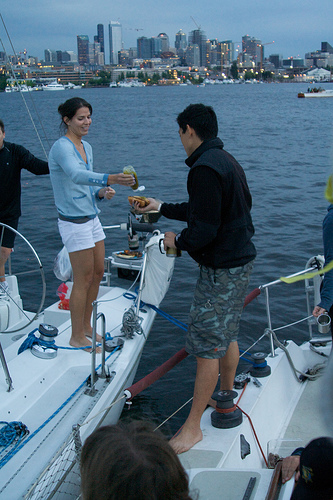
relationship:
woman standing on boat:
[41, 101, 135, 348] [9, 216, 204, 421]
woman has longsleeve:
[41, 101, 135, 348] [56, 149, 114, 187]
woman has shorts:
[41, 101, 135, 348] [46, 217, 119, 251]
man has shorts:
[141, 101, 273, 450] [46, 217, 119, 251]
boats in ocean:
[12, 229, 330, 495] [105, 88, 326, 161]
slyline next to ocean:
[12, 55, 326, 99] [105, 88, 326, 161]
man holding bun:
[141, 101, 273, 450] [125, 192, 157, 209]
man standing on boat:
[141, 101, 273, 450] [9, 216, 204, 421]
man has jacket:
[141, 101, 273, 450] [159, 152, 277, 269]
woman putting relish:
[41, 101, 135, 348] [120, 168, 149, 193]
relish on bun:
[120, 168, 149, 193] [125, 192, 157, 209]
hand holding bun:
[132, 195, 200, 217] [125, 192, 157, 209]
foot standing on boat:
[165, 420, 207, 450] [9, 216, 204, 421]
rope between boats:
[144, 307, 184, 332] [12, 229, 330, 495]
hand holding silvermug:
[157, 183, 244, 247] [154, 233, 190, 267]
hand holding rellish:
[132, 195, 200, 217] [120, 168, 149, 193]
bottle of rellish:
[120, 168, 149, 193] [120, 168, 149, 193]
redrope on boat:
[237, 385, 282, 462] [9, 216, 204, 421]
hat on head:
[295, 434, 331, 500] [270, 437, 330, 499]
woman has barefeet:
[41, 101, 135, 348] [65, 309, 123, 364]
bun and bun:
[125, 192, 157, 209] [125, 192, 157, 209]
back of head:
[183, 101, 226, 136] [270, 437, 330, 499]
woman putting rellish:
[41, 101, 135, 348] [120, 168, 149, 193]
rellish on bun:
[120, 168, 149, 193] [125, 192, 157, 209]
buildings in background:
[28, 33, 299, 74] [10, 33, 329, 82]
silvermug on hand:
[154, 233, 190, 267] [157, 183, 244, 247]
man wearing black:
[141, 101, 273, 450] [4, 149, 32, 229]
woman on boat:
[41, 101, 135, 348] [9, 216, 204, 421]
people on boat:
[12, 229, 330, 495] [9, 216, 204, 421]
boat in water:
[9, 216, 204, 421] [257, 91, 297, 218]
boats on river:
[12, 229, 330, 495] [69, 92, 259, 96]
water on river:
[257, 91, 297, 218] [158, 88, 244, 101]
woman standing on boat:
[41, 101, 135, 348] [117, 258, 331, 500]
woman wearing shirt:
[41, 101, 135, 348] [47, 141, 105, 218]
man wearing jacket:
[141, 101, 273, 450] [159, 152, 277, 269]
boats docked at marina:
[12, 229, 330, 495] [2, 53, 331, 412]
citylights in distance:
[28, 33, 299, 74] [10, 33, 329, 82]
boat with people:
[9, 216, 204, 421] [2, 120, 244, 336]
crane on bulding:
[186, 17, 209, 29] [185, 26, 214, 71]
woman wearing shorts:
[41, 101, 135, 348] [46, 217, 119, 251]